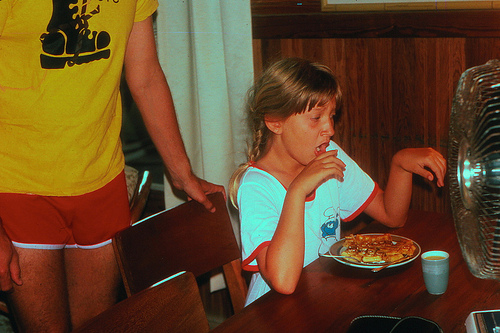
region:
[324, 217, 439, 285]
a plate of food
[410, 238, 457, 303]
a cup of beverage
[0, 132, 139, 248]
red boy shorts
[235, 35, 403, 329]
a little girl wearing a blue shirt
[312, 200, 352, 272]
a blue character on the girl's shirt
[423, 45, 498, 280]
a metal fan on the table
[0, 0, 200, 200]
a man wearing a yellow shirt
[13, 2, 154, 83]
a black roller blade on a shirt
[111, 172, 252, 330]
a wooden chair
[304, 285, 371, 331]
a wooden table in the kitchen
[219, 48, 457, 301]
young girl eating breakfast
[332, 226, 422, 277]
breakfast waffles on plate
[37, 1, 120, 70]
hiking boot print on shirt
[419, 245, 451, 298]
small cup of creamy coffee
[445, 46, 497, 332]
large electric fan on table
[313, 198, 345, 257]
blue smurf on girl's shirt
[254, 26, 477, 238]
lacquered wood siding on wall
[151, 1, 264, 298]
heavy white curtain on door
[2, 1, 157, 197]
yellow shirt on man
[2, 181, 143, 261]
red and white biking shorts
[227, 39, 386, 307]
girl with long blond hair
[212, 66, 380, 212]
girl with hair in braids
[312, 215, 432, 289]
waffle plated on a glass plate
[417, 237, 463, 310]
white cup of some type of beverage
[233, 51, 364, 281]
girl with finger in her mouth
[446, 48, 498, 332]
tabletop electric fan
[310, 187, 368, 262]
white pajamas with smurf on front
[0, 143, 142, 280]
someone with red and white shorts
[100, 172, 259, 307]
brown real wood chair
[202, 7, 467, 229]
brown wood panneling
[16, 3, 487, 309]
a fun meal at the table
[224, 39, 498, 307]
a girl eating by the fan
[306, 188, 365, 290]
she has a Smurf on her shirt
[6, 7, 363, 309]
her older brother is standing behind her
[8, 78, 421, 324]
her brother is wearing shorts from the 80s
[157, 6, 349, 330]
there is a white curtain in the room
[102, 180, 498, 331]
the table is wooden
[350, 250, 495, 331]
the table looks cluttered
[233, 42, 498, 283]
the fan is cooling off the girl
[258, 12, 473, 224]
a wooden panel is in the photo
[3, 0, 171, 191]
yellow t-shirt with a black graphic print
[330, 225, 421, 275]
plate of food on a wooden table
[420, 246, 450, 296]
cup on a wooden table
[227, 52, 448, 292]
blonde hair young girl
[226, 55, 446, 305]
blonde hair girl with a red and white t-shirt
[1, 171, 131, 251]
red shorts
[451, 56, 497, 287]
silver fan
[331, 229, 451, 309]
plate of food and cup on a wooden table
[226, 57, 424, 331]
girl sitting around a table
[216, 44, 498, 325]
young girl with her hand near a fan